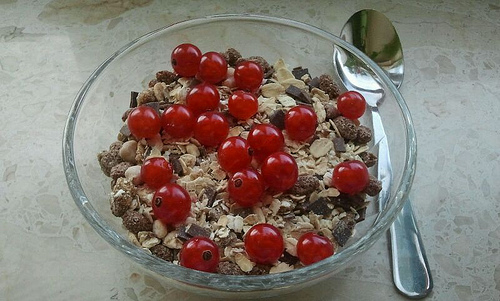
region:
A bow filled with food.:
[46, 8, 441, 291]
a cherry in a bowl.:
[233, 211, 293, 273]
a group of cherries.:
[116, 40, 383, 265]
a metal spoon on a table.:
[329, 0, 434, 298]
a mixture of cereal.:
[195, 160, 205, 183]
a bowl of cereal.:
[52, 14, 454, 282]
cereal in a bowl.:
[99, 42, 390, 255]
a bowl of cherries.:
[55, 11, 430, 299]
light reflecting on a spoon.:
[324, 44, 399, 96]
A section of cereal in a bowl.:
[197, 216, 248, 248]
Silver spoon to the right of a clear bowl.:
[331, 7, 435, 299]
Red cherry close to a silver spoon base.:
[334, 160, 368, 195]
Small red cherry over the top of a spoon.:
[337, 87, 365, 118]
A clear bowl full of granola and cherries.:
[59, 11, 418, 298]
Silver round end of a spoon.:
[333, 6, 405, 102]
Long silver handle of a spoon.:
[362, 107, 432, 297]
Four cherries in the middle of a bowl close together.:
[220, 122, 300, 207]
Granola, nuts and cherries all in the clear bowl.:
[95, 46, 386, 284]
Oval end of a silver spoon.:
[331, 7, 405, 101]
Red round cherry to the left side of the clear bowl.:
[125, 107, 160, 138]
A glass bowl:
[63, 10, 410, 290]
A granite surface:
[5, 3, 499, 299]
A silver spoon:
[325, 10, 447, 291]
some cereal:
[96, 45, 378, 283]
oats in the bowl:
[92, 38, 377, 278]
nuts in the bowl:
[117, 51, 384, 280]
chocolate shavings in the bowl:
[116, 50, 365, 258]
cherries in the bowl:
[116, 37, 374, 278]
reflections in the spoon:
[340, 27, 402, 98]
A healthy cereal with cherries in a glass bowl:
[37, 10, 445, 291]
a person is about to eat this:
[47, 11, 425, 298]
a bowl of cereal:
[57, 18, 427, 299]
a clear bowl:
[56, 10, 427, 295]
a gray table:
[2, 10, 497, 285]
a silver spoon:
[320, 7, 459, 299]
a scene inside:
[14, 8, 488, 291]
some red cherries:
[108, 38, 378, 275]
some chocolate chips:
[115, 44, 395, 279]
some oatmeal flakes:
[110, 43, 378, 277]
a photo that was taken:
[5, 6, 496, 298]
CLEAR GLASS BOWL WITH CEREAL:
[63, 13, 406, 282]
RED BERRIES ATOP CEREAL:
[221, 128, 258, 173]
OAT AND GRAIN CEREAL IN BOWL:
[174, 161, 260, 275]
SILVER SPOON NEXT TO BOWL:
[320, 14, 448, 291]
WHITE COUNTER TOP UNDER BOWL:
[3, 11, 495, 289]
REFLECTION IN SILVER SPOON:
[344, 18, 394, 93]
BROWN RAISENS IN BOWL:
[153, 238, 181, 267]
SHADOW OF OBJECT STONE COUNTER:
[8, 11, 262, 121]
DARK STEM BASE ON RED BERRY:
[151, 196, 163, 208]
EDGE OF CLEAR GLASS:
[50, 179, 142, 269]